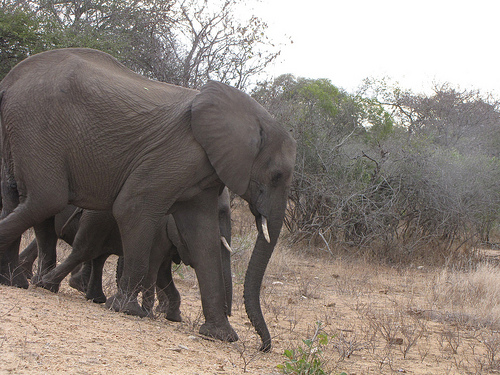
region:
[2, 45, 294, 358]
This is an elephant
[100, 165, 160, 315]
A leg of an elephant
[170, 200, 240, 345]
A leg of an elephant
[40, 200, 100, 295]
A leg of an elephant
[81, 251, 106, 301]
A leg of an elephant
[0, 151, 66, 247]
A leg of an elephant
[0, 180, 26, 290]
A leg of an elephant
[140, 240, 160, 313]
A leg of an elephant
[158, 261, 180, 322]
A leg of an elephant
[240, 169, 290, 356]
Trunk of an elephant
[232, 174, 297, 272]
the tusk is small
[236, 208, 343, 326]
the tusk is small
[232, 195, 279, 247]
the tusk is small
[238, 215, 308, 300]
the tusk is small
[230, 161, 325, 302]
the tusk is small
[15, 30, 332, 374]
Large and small elephant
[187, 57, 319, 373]
Tusks on two elephants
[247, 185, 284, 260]
An elephant's tusk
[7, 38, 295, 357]
Wrinkled skin on an elephant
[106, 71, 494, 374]
Landscape near an elephant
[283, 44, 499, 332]
Bushes with out any leaves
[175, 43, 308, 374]
Elephant ear and trunk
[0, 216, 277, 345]
Many elephant feet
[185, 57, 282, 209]
A large elephant ear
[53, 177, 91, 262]
A baby elephant's tail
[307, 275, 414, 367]
the grass has no leaves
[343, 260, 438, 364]
the grass has no leaves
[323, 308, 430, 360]
the grass has no leaves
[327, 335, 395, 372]
the grass has no leaves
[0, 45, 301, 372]
two elephants walking down a hill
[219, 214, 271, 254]
two tusks on the elephants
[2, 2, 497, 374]
elephants in the safari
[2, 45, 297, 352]
two dark grey elephants walking in the woods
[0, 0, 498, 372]
two elephants taking a walk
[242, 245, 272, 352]
the trunk of an elephant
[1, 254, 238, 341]
the elephants' feet on the ground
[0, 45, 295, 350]
an elephant looking at the ground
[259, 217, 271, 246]
a white tusk on the right side of the elephant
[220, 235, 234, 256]
the tusk of the elephant beside another elephant